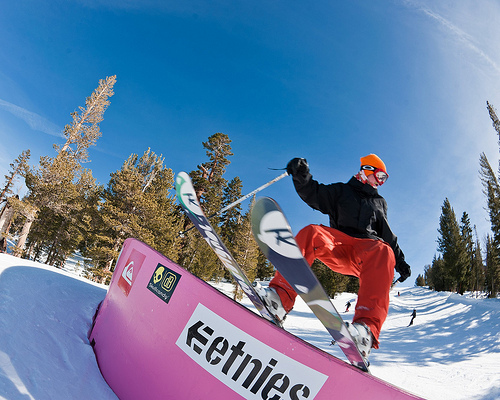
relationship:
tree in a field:
[97, 146, 181, 291] [2, 244, 494, 399]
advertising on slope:
[174, 302, 328, 397] [1, 248, 498, 398]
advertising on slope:
[141, 262, 182, 312] [1, 248, 498, 398]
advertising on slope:
[110, 244, 147, 295] [1, 248, 498, 398]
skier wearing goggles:
[249, 151, 411, 368] [342, 160, 392, 182]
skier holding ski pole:
[249, 151, 411, 368] [174, 140, 314, 255]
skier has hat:
[249, 151, 411, 368] [355, 150, 389, 177]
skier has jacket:
[244, 151, 409, 368] [280, 169, 417, 263]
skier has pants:
[244, 151, 409, 368] [255, 216, 422, 353]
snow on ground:
[374, 283, 484, 398] [262, 274, 497, 398]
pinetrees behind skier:
[440, 183, 496, 285] [244, 151, 409, 368]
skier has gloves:
[244, 151, 409, 368] [233, 132, 330, 208]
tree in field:
[0, 148, 30, 206] [0, 83, 290, 275]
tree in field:
[42, 137, 102, 272] [0, 83, 290, 275]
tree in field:
[181, 132, 233, 280] [1, 62, 281, 293]